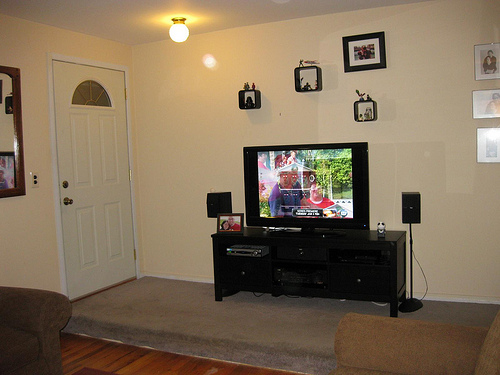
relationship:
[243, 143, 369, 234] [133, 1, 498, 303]
tv near wall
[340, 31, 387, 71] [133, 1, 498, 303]
picture frame on wall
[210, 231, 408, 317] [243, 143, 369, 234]
stand under tv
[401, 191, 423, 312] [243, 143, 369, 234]
speaker beside tv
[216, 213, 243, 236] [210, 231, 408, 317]
picture frame on stand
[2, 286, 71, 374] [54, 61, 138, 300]
chair near door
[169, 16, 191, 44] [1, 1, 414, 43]
light on ceiling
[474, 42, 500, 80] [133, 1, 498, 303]
picture on wall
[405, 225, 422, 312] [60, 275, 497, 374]
speaker stand on floor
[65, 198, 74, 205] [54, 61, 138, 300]
handle for door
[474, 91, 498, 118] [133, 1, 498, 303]
picture on wall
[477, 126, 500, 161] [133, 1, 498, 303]
picture on wall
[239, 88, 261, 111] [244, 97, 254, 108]
shelf with ornaments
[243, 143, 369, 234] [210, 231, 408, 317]
tv on stand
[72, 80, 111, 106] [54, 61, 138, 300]
window in door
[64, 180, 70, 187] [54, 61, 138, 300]
lock on door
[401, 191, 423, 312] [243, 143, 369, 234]
speaker next to tv